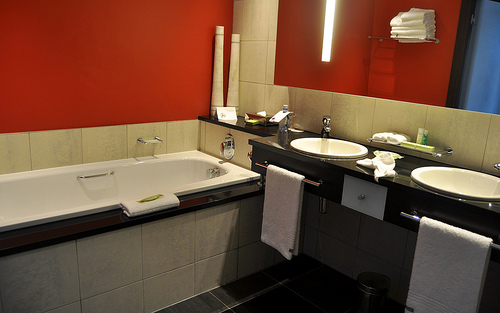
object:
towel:
[405, 215, 492, 311]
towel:
[390, 11, 435, 26]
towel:
[390, 24, 434, 30]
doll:
[271, 0, 361, 94]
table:
[297, 120, 498, 235]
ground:
[403, 106, 447, 167]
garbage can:
[355, 271, 391, 311]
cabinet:
[243, 145, 497, 255]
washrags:
[372, 129, 406, 144]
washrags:
[358, 154, 405, 180]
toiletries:
[412, 124, 432, 147]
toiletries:
[240, 109, 270, 126]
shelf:
[369, 137, 451, 161]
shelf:
[369, 37, 438, 52]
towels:
[381, 33, 446, 43]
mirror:
[281, 0, 493, 109]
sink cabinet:
[273, 134, 369, 160]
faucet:
[320, 113, 333, 142]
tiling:
[0, 115, 255, 174]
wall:
[0, 0, 292, 175]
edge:
[336, 89, 358, 96]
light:
[316, 0, 341, 66]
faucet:
[213, 130, 237, 162]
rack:
[252, 157, 321, 191]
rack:
[399, 207, 498, 255]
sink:
[409, 160, 499, 204]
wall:
[230, 4, 277, 120]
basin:
[289, 132, 375, 162]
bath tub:
[3, 145, 259, 237]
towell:
[257, 164, 297, 259]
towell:
[397, 212, 494, 310]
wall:
[283, 9, 452, 98]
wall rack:
[390, 31, 439, 45]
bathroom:
[3, 7, 445, 311]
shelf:
[358, 28, 445, 48]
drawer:
[331, 165, 400, 223]